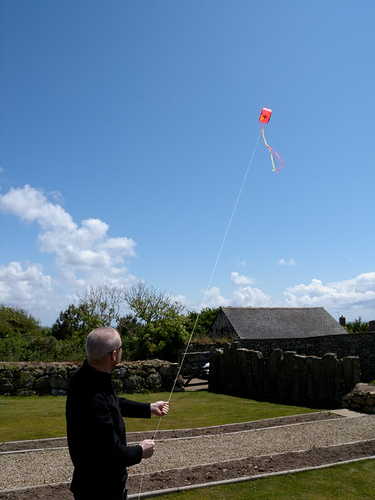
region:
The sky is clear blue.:
[11, 9, 373, 206]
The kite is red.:
[241, 100, 305, 196]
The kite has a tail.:
[245, 95, 306, 193]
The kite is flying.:
[235, 88, 301, 193]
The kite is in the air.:
[235, 80, 295, 178]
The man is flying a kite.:
[48, 304, 244, 497]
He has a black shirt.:
[54, 299, 183, 499]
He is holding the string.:
[38, 57, 310, 494]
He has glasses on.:
[69, 318, 133, 366]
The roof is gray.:
[225, 304, 346, 338]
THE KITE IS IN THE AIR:
[256, 102, 281, 124]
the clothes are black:
[61, 374, 158, 488]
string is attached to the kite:
[256, 125, 267, 152]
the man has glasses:
[57, 317, 169, 498]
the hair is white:
[88, 322, 123, 355]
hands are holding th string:
[126, 401, 185, 463]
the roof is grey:
[250, 306, 332, 334]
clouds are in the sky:
[51, 232, 120, 277]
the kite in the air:
[249, 88, 287, 175]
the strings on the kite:
[259, 124, 286, 171]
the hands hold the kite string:
[136, 393, 171, 461]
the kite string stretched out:
[164, 140, 263, 403]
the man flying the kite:
[55, 301, 174, 498]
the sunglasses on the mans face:
[106, 337, 122, 365]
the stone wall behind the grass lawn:
[1, 360, 66, 401]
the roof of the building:
[222, 304, 339, 341]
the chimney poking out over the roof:
[336, 313, 347, 330]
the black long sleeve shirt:
[65, 362, 141, 498]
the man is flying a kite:
[74, 90, 280, 482]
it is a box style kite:
[247, 97, 289, 181]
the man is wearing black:
[61, 309, 141, 497]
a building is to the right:
[215, 297, 355, 374]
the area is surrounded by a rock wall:
[14, 347, 359, 393]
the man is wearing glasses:
[96, 330, 138, 367]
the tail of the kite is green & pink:
[258, 108, 280, 179]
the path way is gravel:
[0, 410, 357, 457]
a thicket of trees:
[15, 310, 178, 355]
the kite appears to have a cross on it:
[245, 100, 281, 133]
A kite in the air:
[264, 111, 266, 121]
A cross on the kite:
[263, 114, 267, 118]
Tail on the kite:
[272, 155, 274, 165]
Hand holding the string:
[161, 403, 165, 413]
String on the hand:
[167, 399, 168, 401]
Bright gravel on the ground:
[195, 441, 212, 454]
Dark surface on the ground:
[211, 468, 239, 475]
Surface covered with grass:
[201, 405, 230, 417]